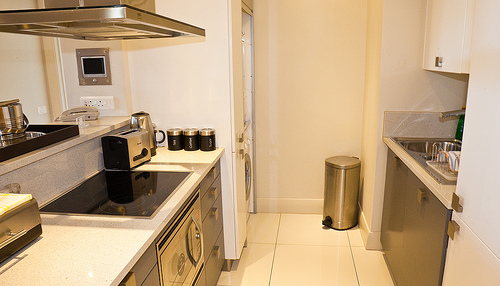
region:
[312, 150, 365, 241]
Trash can pedal operated.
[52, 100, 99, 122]
Telehone is land wired.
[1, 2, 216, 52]
Overhead exhaust system for fumes.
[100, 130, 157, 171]
Toaster always useful appliance.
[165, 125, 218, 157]
Three canisters on counter.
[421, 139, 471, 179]
Dish rack ready for dishes.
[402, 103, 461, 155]
Stainless steel sink and faucet.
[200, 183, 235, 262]
Drawers used for utensils.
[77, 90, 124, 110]
Electrical outlets on wall.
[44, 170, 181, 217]
Stove top uses electric.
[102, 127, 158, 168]
a silver and black toaster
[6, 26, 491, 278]
kitchen with stainless steal appliances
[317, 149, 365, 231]
a silver trash can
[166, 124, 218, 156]
silver and black containers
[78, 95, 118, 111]
two white outlets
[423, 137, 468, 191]
a dish rack next to the sink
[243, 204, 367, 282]
a white tile floor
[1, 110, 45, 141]
a silver handle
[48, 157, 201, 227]
a black stove top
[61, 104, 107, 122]
a white house phone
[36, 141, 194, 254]
a glass cooktop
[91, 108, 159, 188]
a two slice toaster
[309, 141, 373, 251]
a metal trash bin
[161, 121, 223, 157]
three piece canister set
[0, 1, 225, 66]
a large exhaust fan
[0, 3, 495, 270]
a neat kitchen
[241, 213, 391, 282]
a floor of white tiles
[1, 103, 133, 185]
a shelf behind the counter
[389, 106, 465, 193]
a sink of stainless steel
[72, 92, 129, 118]
large grouping of electrical outlets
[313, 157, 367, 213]
the trash can is silver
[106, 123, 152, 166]
the toaster is on the table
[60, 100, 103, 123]
the telephone is white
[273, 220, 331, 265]
the floor is tiled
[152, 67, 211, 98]
the wall is white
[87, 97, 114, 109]
the sockets are empty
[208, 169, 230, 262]
the cabinets have handles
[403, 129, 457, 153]
the sink is silver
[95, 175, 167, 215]
the cooker has a glassy surface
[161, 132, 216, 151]
there are cups against the wall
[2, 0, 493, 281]
Kitchen inside of an apartment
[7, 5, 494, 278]
Kitchen inside of a condo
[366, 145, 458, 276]
White kitchen with grey cabinets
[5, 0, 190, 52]
Kitchen with stainless steel hood.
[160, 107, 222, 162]
Black containers with stainless steel tops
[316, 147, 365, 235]
Stainless steel garbage can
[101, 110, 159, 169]
Stainless steel toaster and cofee maker sitting on countertop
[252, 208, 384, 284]
White tiled floor in a white kitchen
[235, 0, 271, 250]
Washer and dryer closet are in the kitchen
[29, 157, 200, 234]
Glass flat-top stove inside of a white kitchen